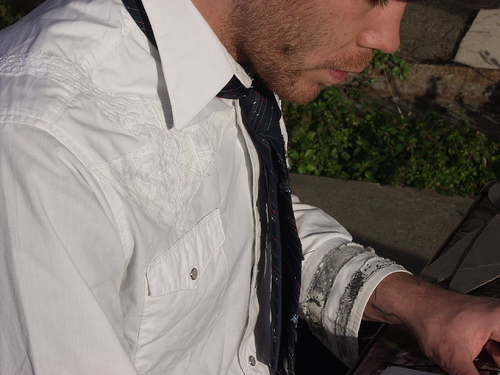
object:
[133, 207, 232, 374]
pocket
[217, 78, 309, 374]
tie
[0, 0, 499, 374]
man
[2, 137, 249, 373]
white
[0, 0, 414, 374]
shirt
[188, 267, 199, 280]
button